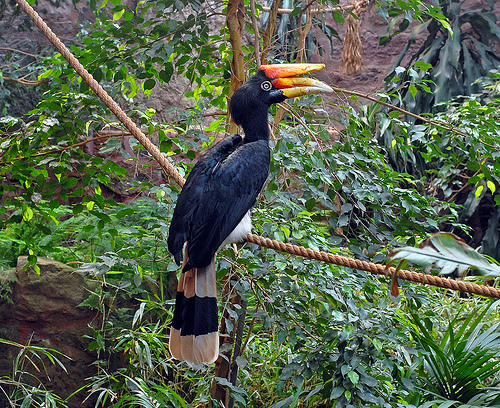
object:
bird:
[166, 63, 337, 367]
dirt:
[0, 1, 500, 240]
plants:
[251, 0, 346, 65]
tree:
[0, 1, 500, 407]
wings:
[178, 139, 271, 276]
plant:
[363, 61, 437, 172]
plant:
[393, 306, 498, 407]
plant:
[0, 330, 75, 408]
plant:
[112, 371, 176, 407]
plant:
[370, 0, 500, 264]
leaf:
[280, 361, 295, 383]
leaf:
[444, 309, 459, 356]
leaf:
[140, 79, 158, 92]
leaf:
[20, 203, 35, 224]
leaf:
[130, 339, 146, 372]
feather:
[234, 179, 244, 200]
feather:
[220, 186, 230, 200]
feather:
[207, 197, 215, 212]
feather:
[214, 212, 222, 227]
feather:
[217, 164, 234, 188]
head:
[223, 59, 333, 125]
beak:
[272, 74, 335, 99]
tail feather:
[179, 271, 197, 369]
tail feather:
[192, 257, 219, 367]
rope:
[16, 0, 500, 300]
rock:
[11, 251, 104, 326]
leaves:
[26, 253, 41, 272]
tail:
[167, 243, 220, 368]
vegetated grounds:
[205, 301, 263, 407]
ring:
[259, 81, 277, 92]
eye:
[260, 80, 275, 93]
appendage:
[255, 60, 328, 77]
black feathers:
[188, 209, 223, 269]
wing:
[165, 133, 243, 268]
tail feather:
[168, 269, 186, 360]